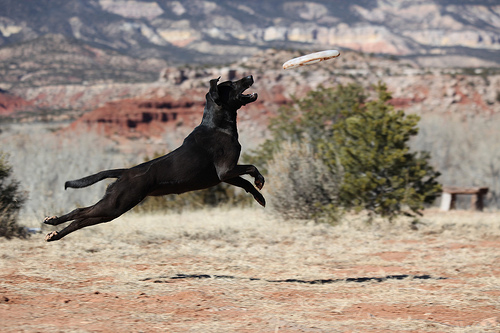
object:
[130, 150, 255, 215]
tree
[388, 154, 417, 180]
leaves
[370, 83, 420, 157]
branches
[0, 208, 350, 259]
grass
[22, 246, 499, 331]
sand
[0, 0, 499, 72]
hillside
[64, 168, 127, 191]
tail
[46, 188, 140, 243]
leg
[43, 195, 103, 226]
leg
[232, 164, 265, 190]
leg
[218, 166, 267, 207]
leg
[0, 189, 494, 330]
area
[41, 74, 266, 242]
dog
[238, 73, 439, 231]
shrubbery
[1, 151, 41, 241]
shrubbery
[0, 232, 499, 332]
dirt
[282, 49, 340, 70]
fisbee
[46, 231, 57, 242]
paw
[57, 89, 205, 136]
red rocks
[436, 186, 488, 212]
bench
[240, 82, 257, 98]
mouth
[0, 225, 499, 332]
ground